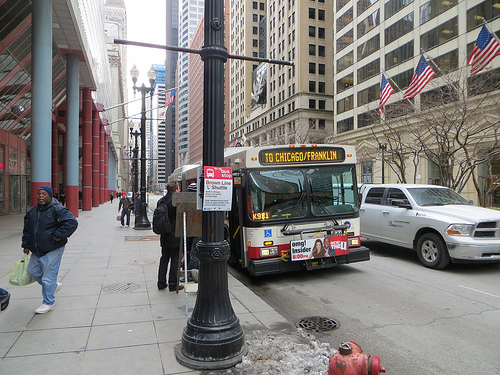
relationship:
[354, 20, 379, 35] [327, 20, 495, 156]
window on building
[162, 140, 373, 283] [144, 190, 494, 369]
bus on street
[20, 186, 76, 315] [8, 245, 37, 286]
male holding bag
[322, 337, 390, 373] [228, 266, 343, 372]
hydrant on curb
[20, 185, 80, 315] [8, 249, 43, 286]
male carrying bag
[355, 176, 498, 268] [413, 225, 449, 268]
vehicle has tire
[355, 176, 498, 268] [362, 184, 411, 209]
vehicle has window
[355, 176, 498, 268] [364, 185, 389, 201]
vehicle has window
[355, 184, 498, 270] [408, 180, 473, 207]
vehicle has window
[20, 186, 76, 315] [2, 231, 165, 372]
male on sidewalk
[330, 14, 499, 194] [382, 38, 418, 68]
building has window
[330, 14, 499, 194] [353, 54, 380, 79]
building has window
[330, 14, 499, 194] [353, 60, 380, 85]
building has window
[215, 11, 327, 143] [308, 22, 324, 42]
building has window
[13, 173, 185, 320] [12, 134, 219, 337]
people in outdoors